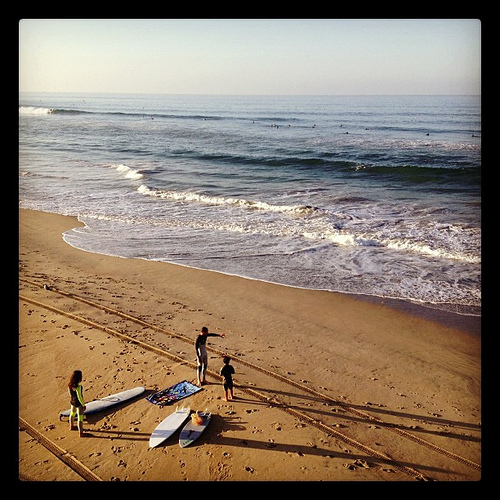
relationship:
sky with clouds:
[19, 19, 479, 94] [273, 42, 343, 82]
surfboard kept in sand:
[148, 407, 191, 448] [243, 400, 320, 485]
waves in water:
[18, 100, 483, 264] [18, 94, 480, 316]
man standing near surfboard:
[194, 326, 226, 387] [82, 377, 203, 441]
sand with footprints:
[467, 247, 488, 497] [19, 246, 477, 478]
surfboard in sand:
[149, 405, 191, 445] [249, 325, 461, 467]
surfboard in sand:
[59, 384, 146, 414] [249, 325, 461, 467]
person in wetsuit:
[68, 369, 87, 437] [65, 382, 85, 419]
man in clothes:
[194, 326, 226, 387] [198, 342, 207, 359]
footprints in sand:
[19, 246, 477, 478] [25, 215, 474, 479]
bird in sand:
[40, 281, 52, 291] [69, 261, 176, 365]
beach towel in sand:
[146, 380, 205, 408] [25, 215, 474, 479]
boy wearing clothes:
[219, 356, 234, 403] [221, 363, 233, 390]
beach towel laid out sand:
[145, 379, 203, 407] [25, 215, 474, 479]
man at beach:
[194, 326, 226, 387] [21, 201, 496, 477]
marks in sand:
[32, 281, 454, 469] [20, 245, 478, 480]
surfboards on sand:
[57, 380, 215, 452] [25, 215, 474, 479]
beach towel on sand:
[145, 379, 203, 407] [25, 215, 474, 479]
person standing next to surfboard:
[69, 372, 89, 429] [70, 390, 152, 404]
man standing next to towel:
[194, 326, 226, 387] [147, 364, 202, 409]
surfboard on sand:
[58, 386, 145, 423] [25, 215, 474, 479]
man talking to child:
[194, 327, 224, 384] [219, 359, 236, 401]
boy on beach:
[219, 356, 236, 402] [19, 90, 483, 480]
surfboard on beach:
[58, 386, 145, 423] [21, 201, 496, 477]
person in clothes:
[68, 369, 87, 437] [68, 383, 85, 408]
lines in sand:
[42, 276, 142, 351] [29, 271, 449, 489]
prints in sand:
[255, 325, 296, 387] [251, 378, 399, 452]